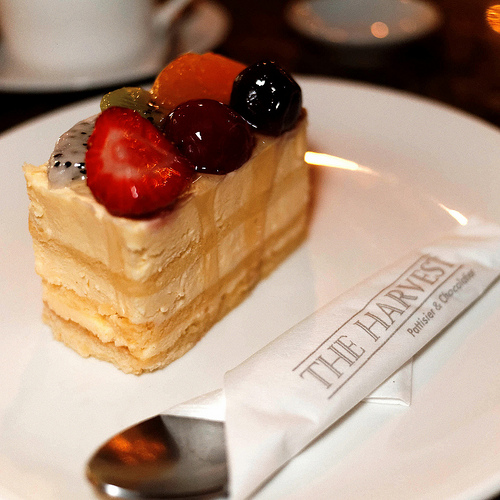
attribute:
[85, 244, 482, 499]
spoon — silver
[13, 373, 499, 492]
dessert — here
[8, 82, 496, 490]
plate — white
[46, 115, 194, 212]
strawberries — here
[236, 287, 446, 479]
napkin — white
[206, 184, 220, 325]
fruit juices — dripping, running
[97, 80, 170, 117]
kiwi — here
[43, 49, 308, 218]
mixed fruit — here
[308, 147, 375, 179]
light — shining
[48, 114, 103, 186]
raspberry — black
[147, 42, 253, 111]
dragonfruit — here